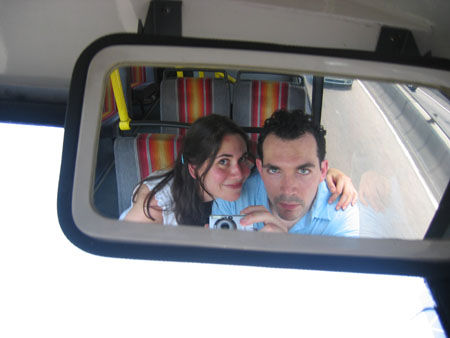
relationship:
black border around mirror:
[57, 32, 450, 278] [91, 63, 449, 242]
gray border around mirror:
[71, 44, 449, 262] [91, 63, 449, 242]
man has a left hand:
[206, 109, 361, 237] [240, 204, 289, 233]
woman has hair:
[119, 115, 358, 228] [132, 113, 257, 226]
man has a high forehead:
[206, 109, 361, 237] [260, 129, 318, 169]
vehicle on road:
[307, 74, 353, 87] [304, 73, 440, 241]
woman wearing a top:
[119, 115, 358, 228] [118, 167, 181, 227]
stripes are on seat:
[177, 75, 213, 134] [160, 67, 230, 134]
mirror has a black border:
[91, 63, 449, 242] [57, 32, 450, 278]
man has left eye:
[206, 109, 361, 237] [297, 167, 311, 175]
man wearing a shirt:
[206, 109, 361, 237] [212, 167, 359, 238]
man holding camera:
[206, 109, 361, 237] [208, 214, 254, 231]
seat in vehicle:
[160, 67, 230, 134] [0, 0, 449, 338]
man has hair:
[206, 109, 361, 237] [257, 109, 327, 171]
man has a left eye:
[206, 109, 361, 237] [297, 167, 311, 175]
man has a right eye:
[206, 109, 361, 237] [267, 168, 281, 175]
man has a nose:
[206, 109, 361, 237] [280, 169, 297, 195]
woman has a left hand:
[119, 115, 358, 228] [325, 165, 358, 211]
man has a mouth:
[206, 109, 361, 237] [278, 200, 301, 209]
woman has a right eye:
[119, 115, 358, 228] [216, 158, 230, 166]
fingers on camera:
[239, 204, 286, 233] [208, 214, 254, 231]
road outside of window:
[304, 73, 440, 241] [304, 74, 449, 238]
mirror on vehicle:
[91, 63, 449, 242] [0, 0, 449, 338]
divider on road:
[360, 78, 450, 201] [304, 73, 440, 241]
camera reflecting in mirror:
[208, 214, 254, 231] [91, 63, 449, 242]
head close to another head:
[181, 113, 250, 201] [255, 108, 328, 221]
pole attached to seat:
[110, 68, 131, 131] [112, 119, 192, 218]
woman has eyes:
[119, 115, 358, 228] [218, 156, 247, 165]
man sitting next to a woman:
[206, 109, 361, 237] [119, 115, 358, 228]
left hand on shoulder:
[325, 165, 358, 211] [318, 180, 359, 237]